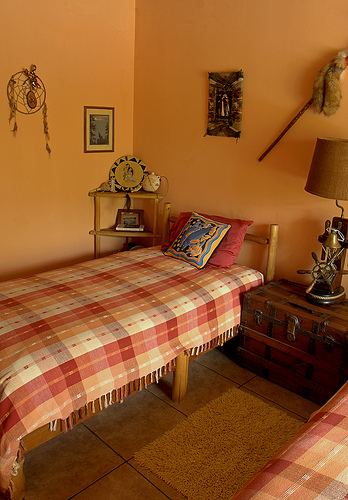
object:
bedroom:
[1, 0, 347, 498]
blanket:
[229, 378, 345, 498]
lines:
[70, 418, 163, 498]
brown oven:
[82, 101, 116, 156]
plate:
[108, 155, 146, 192]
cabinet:
[239, 286, 348, 406]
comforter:
[75, 295, 172, 365]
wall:
[146, 67, 184, 116]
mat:
[136, 385, 306, 498]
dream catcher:
[6, 64, 51, 155]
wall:
[124, 47, 136, 137]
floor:
[0, 333, 347, 498]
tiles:
[43, 438, 119, 498]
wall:
[58, 228, 86, 251]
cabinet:
[89, 182, 171, 258]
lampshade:
[303, 136, 347, 202]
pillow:
[164, 210, 232, 271]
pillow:
[160, 208, 252, 269]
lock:
[286, 315, 301, 343]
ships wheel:
[296, 250, 348, 305]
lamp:
[297, 138, 347, 309]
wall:
[301, 7, 346, 41]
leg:
[173, 351, 189, 402]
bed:
[0, 206, 281, 496]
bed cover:
[0, 236, 264, 485]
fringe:
[42, 340, 80, 391]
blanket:
[0, 235, 277, 498]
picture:
[203, 69, 242, 145]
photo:
[114, 208, 142, 225]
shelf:
[89, 223, 165, 236]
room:
[1, 1, 346, 498]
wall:
[7, 232, 18, 278]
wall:
[15, 179, 29, 229]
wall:
[90, 36, 129, 100]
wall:
[209, 159, 219, 206]